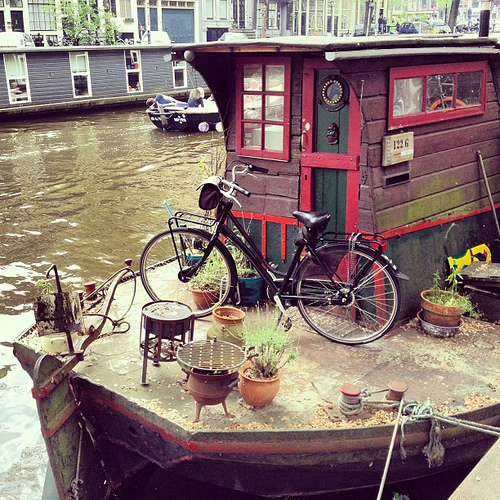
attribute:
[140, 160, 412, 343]
bike — black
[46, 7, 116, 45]
greenleaves — green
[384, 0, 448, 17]
greenleaves — green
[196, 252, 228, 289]
greenleaves — green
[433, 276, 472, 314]
greenleaves — green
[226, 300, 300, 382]
greenleaves — green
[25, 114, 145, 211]
water — ripples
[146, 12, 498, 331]
building — red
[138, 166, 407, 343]
bicycle — black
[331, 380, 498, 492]
rope — white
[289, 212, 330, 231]
seat — black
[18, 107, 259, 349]
water — blue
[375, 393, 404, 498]
rope — white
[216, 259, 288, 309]
bucket — blue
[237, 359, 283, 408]
pot — brown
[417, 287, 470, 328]
pot — brown